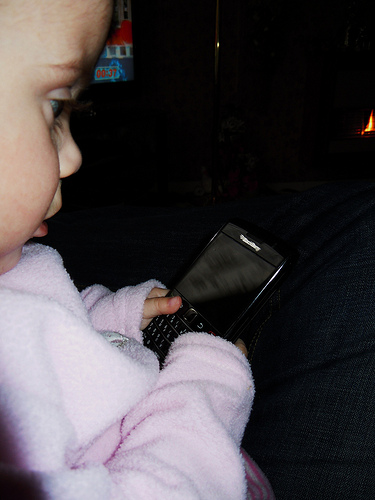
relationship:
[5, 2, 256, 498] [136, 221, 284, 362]
baby holding phone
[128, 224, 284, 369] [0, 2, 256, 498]
blackberry held baby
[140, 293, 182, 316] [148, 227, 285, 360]
thumb on phone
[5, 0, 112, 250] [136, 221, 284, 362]
face watching phone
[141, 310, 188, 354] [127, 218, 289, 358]
keyboard on blackberry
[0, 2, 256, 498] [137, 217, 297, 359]
baby on cellphone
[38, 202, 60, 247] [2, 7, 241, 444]
lips of child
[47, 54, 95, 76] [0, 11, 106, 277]
eyebrow of head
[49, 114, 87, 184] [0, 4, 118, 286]
nose on face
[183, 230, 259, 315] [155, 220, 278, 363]
screen of phone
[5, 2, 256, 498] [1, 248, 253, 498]
baby wearing clothes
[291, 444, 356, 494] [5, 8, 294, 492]
blue jeans under baby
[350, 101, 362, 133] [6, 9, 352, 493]
fireplace in shot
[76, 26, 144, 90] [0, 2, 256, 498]
television behind baby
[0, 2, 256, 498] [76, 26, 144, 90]
baby sitting in front of television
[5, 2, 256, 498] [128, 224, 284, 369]
baby holding blackberry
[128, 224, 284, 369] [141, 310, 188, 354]
blackberry has keyboard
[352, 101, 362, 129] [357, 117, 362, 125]
fireplace has fire